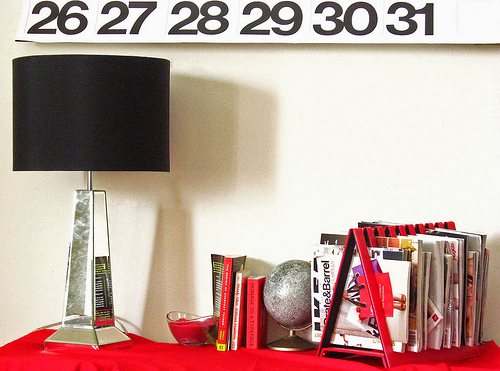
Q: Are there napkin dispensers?
A: No, there are no napkin dispensers.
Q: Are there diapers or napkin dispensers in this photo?
A: No, there are no napkin dispensers or diapers.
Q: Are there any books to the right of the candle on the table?
A: Yes, there is a book to the right of the candle.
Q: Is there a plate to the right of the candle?
A: No, there is a book to the right of the candle.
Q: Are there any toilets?
A: No, there are no toilets.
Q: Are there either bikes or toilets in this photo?
A: No, there are no toilets or bikes.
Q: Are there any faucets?
A: No, there are no faucets.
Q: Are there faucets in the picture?
A: No, there are no faucets.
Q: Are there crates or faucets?
A: No, there are no faucets or crates.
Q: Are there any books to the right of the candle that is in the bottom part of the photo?
A: Yes, there is a book to the right of the candle.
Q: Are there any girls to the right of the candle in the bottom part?
A: No, there is a book to the right of the candle.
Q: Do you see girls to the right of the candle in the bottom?
A: No, there is a book to the right of the candle.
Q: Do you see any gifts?
A: No, there are no gifts.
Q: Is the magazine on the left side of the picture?
A: No, the magazine is on the right of the image.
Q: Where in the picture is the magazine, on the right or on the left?
A: The magazine is on the right of the image.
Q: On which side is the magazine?
A: The magazine is on the right of the image.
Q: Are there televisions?
A: No, there are no televisions.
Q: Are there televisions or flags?
A: No, there are no televisions or flags.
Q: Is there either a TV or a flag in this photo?
A: No, there are no televisions or flags.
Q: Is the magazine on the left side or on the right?
A: The magazine is on the right of the image.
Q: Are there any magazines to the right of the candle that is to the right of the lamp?
A: Yes, there is a magazine to the right of the candle.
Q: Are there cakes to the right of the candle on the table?
A: No, there is a magazine to the right of the candle.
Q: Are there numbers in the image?
A: Yes, there are numbers.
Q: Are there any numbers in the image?
A: Yes, there are numbers.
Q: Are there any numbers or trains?
A: Yes, there are numbers.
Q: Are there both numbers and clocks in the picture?
A: No, there are numbers but no clocks.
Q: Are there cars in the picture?
A: No, there are no cars.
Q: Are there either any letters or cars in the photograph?
A: No, there are no cars or letters.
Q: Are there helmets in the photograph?
A: No, there are no helmets.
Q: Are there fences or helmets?
A: No, there are no helmets or fences.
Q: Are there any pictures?
A: No, there are no pictures.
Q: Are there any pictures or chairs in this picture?
A: No, there are no pictures or chairs.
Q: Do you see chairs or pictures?
A: No, there are no pictures or chairs.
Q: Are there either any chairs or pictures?
A: No, there are no pictures or chairs.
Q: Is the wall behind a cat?
A: No, the wall is behind a magazine.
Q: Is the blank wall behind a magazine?
A: Yes, the wall is behind a magazine.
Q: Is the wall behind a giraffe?
A: No, the wall is behind a magazine.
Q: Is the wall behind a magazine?
A: Yes, the wall is behind a magazine.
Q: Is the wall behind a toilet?
A: No, the wall is behind a magazine.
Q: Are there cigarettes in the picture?
A: No, there are no cigarettes.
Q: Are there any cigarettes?
A: No, there are no cigarettes.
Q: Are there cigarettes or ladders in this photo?
A: No, there are no cigarettes or ladders.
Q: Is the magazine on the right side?
A: Yes, the magazine is on the right of the image.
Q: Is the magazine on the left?
A: No, the magazine is on the right of the image.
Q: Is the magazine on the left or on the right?
A: The magazine is on the right of the image.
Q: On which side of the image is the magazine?
A: The magazine is on the right of the image.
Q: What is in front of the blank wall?
A: The magazine is in front of the wall.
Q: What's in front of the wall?
A: The magazine is in front of the wall.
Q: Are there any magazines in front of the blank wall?
A: Yes, there is a magazine in front of the wall.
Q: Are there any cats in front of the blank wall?
A: No, there is a magazine in front of the wall.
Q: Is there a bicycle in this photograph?
A: No, there are no bicycles.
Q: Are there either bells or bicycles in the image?
A: No, there are no bicycles or bells.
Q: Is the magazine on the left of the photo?
A: No, the magazine is on the right of the image.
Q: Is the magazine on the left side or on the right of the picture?
A: The magazine is on the right of the image.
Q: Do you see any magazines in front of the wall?
A: Yes, there is a magazine in front of the wall.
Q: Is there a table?
A: Yes, there is a table.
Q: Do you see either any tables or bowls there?
A: Yes, there is a table.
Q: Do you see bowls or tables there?
A: Yes, there is a table.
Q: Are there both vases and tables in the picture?
A: No, there is a table but no vases.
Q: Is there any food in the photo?
A: No, there is no food.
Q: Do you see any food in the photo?
A: No, there is no food.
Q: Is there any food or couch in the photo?
A: No, there are no food or couches.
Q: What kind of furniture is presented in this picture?
A: The furniture is a table.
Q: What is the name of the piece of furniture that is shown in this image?
A: The piece of furniture is a table.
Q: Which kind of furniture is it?
A: The piece of furniture is a table.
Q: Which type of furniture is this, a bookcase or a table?
A: That is a table.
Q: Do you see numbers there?
A: Yes, there are numbers.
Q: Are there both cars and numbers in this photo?
A: No, there are numbers but no cars.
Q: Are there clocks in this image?
A: No, there are no clocks.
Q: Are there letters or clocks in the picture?
A: No, there are no clocks or letters.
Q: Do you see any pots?
A: No, there are no pots.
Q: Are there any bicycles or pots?
A: No, there are no pots or bicycles.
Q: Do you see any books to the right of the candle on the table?
A: Yes, there is a book to the right of the candle.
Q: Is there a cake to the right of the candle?
A: No, there is a book to the right of the candle.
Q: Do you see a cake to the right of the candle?
A: No, there is a book to the right of the candle.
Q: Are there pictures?
A: No, there are no pictures.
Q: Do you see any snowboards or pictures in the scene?
A: No, there are no pictures or snowboards.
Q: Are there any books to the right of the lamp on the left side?
A: Yes, there is a book to the right of the lamp.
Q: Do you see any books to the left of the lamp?
A: No, the book is to the right of the lamp.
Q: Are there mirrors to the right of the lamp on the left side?
A: No, there is a book to the right of the lamp.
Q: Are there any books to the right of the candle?
A: Yes, there is a book to the right of the candle.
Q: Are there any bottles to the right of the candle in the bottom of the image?
A: No, there is a book to the right of the candle.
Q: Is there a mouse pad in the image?
A: No, there are no mouse pads.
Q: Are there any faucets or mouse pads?
A: No, there are no mouse pads or faucets.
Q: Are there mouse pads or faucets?
A: No, there are no mouse pads or faucets.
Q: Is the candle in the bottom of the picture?
A: Yes, the candle is in the bottom of the image.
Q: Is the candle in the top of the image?
A: No, the candle is in the bottom of the image.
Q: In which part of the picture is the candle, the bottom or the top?
A: The candle is in the bottom of the image.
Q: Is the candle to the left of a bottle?
A: No, the candle is to the left of a book.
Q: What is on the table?
A: The candle is on the table.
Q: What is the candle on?
A: The candle is on the table.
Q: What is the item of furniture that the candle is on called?
A: The piece of furniture is a table.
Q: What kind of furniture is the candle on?
A: The candle is on the table.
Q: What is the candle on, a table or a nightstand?
A: The candle is on a table.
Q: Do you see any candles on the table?
A: Yes, there is a candle on the table.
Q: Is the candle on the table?
A: Yes, the candle is on the table.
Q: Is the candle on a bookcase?
A: No, the candle is on the table.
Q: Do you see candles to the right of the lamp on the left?
A: Yes, there is a candle to the right of the lamp.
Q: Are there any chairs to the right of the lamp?
A: No, there is a candle to the right of the lamp.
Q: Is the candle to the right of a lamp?
A: Yes, the candle is to the right of a lamp.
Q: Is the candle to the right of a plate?
A: No, the candle is to the right of a lamp.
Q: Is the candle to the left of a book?
A: Yes, the candle is to the left of a book.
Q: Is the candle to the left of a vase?
A: No, the candle is to the left of a book.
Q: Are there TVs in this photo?
A: No, there are no tvs.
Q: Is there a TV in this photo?
A: No, there are no televisions.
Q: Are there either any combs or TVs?
A: No, there are no TVs or combs.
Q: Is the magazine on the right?
A: Yes, the magazine is on the right of the image.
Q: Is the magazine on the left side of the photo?
A: No, the magazine is on the right of the image.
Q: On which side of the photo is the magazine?
A: The magazine is on the right of the image.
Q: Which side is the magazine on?
A: The magazine is on the right of the image.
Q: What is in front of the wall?
A: The magazine is in front of the wall.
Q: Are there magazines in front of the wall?
A: Yes, there is a magazine in front of the wall.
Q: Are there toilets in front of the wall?
A: No, there is a magazine in front of the wall.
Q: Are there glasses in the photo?
A: No, there are no glasses.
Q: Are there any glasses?
A: No, there are no glasses.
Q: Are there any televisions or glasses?
A: No, there are no glasses or televisions.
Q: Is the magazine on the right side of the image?
A: Yes, the magazine is on the right of the image.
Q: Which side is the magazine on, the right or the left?
A: The magazine is on the right of the image.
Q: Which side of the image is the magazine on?
A: The magazine is on the right of the image.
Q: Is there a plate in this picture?
A: No, there are no plates.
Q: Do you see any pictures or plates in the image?
A: No, there are no plates or pictures.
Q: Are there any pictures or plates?
A: No, there are no plates or pictures.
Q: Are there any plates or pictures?
A: No, there are no plates or pictures.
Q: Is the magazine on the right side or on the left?
A: The magazine is on the right of the image.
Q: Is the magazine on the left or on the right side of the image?
A: The magazine is on the right of the image.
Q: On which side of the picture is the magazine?
A: The magazine is on the right of the image.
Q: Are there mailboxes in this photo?
A: No, there are no mailboxes.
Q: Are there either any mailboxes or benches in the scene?
A: No, there are no mailboxes or benches.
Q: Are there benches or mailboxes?
A: No, there are no mailboxes or benches.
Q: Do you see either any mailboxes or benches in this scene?
A: No, there are no mailboxes or benches.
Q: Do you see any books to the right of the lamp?
A: Yes, there is a book to the right of the lamp.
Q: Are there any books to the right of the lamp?
A: Yes, there is a book to the right of the lamp.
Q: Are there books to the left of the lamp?
A: No, the book is to the right of the lamp.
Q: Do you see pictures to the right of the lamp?
A: No, there is a book to the right of the lamp.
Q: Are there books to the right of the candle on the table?
A: Yes, there is a book to the right of the candle.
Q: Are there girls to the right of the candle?
A: No, there is a book to the right of the candle.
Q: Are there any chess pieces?
A: No, there are no chess pieces.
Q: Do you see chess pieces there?
A: No, there are no chess pieces.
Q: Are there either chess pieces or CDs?
A: No, there are no chess pieces or cds.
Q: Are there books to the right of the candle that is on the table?
A: Yes, there is a book to the right of the candle.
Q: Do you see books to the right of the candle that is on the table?
A: Yes, there is a book to the right of the candle.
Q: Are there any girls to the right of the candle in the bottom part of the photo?
A: No, there is a book to the right of the candle.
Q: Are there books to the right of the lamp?
A: Yes, there is a book to the right of the lamp.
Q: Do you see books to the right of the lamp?
A: Yes, there is a book to the right of the lamp.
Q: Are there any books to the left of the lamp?
A: No, the book is to the right of the lamp.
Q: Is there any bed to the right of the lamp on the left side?
A: No, there is a book to the right of the lamp.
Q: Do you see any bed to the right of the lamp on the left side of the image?
A: No, there is a book to the right of the lamp.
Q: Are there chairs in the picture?
A: No, there are no chairs.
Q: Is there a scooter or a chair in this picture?
A: No, there are no chairs or scooters.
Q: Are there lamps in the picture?
A: Yes, there is a lamp.